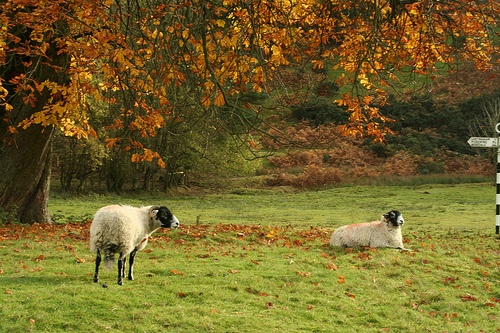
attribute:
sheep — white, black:
[328, 209, 408, 249]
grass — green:
[55, 283, 283, 330]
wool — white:
[87, 196, 167, 261]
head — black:
[123, 200, 182, 246]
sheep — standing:
[55, 200, 214, 276]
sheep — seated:
[298, 186, 439, 267]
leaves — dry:
[181, 213, 312, 263]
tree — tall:
[5, 49, 115, 257]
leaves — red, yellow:
[192, 215, 307, 269]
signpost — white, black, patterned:
[468, 145, 498, 253]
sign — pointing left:
[455, 133, 495, 150]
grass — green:
[133, 273, 356, 325]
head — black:
[146, 198, 180, 236]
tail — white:
[95, 222, 113, 263]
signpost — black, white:
[464, 118, 498, 238]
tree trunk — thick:
[6, 11, 80, 232]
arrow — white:
[464, 133, 498, 153]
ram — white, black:
[84, 196, 185, 288]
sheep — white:
[81, 193, 184, 289]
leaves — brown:
[195, 220, 316, 245]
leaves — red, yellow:
[8, 7, 497, 163]